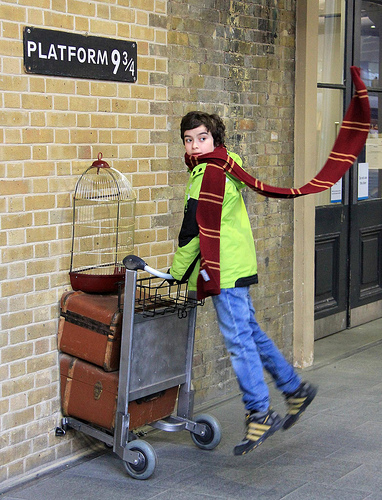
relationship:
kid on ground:
[165, 110, 317, 455] [4, 318, 379, 498]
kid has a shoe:
[165, 110, 317, 455] [277, 380, 321, 432]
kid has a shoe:
[165, 110, 317, 455] [231, 404, 285, 458]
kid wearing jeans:
[165, 110, 317, 455] [208, 278, 314, 422]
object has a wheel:
[60, 258, 232, 483] [121, 438, 160, 477]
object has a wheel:
[60, 258, 232, 483] [187, 414, 222, 452]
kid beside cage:
[165, 110, 317, 455] [67, 151, 142, 294]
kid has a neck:
[165, 110, 317, 455] [184, 153, 221, 167]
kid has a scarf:
[165, 110, 317, 455] [167, 67, 377, 309]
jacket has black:
[165, 149, 264, 294] [172, 206, 260, 288]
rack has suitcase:
[60, 258, 232, 483] [58, 290, 129, 372]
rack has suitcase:
[60, 258, 232, 483] [53, 351, 183, 437]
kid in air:
[165, 110, 317, 455] [0, 9, 380, 497]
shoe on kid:
[277, 380, 321, 432] [165, 110, 317, 455]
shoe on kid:
[231, 404, 285, 458] [165, 110, 317, 455]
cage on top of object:
[67, 151, 142, 294] [60, 258, 232, 483]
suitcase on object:
[58, 290, 129, 372] [60, 258, 232, 483]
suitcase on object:
[53, 351, 183, 437] [60, 258, 232, 483]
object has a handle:
[60, 258, 232, 483] [120, 254, 193, 281]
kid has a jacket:
[165, 110, 317, 455] [165, 149, 264, 294]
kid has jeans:
[165, 110, 317, 455] [208, 278, 314, 422]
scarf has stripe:
[167, 67, 377, 309] [325, 148, 356, 160]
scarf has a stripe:
[167, 67, 377, 309] [336, 115, 372, 127]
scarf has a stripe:
[167, 67, 377, 309] [257, 174, 269, 192]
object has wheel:
[60, 258, 232, 483] [121, 438, 160, 477]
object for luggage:
[60, 258, 232, 483] [53, 351, 183, 437]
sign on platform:
[21, 23, 143, 84] [6, 5, 378, 499]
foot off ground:
[231, 404, 285, 458] [4, 318, 379, 498]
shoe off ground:
[277, 380, 321, 432] [4, 318, 379, 498]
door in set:
[312, 0, 350, 351] [314, 3, 380, 350]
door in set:
[346, 4, 380, 329] [314, 3, 380, 350]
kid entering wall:
[165, 110, 317, 455] [0, 1, 306, 491]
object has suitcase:
[60, 258, 232, 483] [58, 290, 129, 372]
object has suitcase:
[60, 258, 232, 483] [53, 351, 183, 437]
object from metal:
[116, 436, 158, 481] [60, 258, 232, 483]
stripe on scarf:
[325, 148, 356, 160] [167, 67, 377, 309]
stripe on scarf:
[336, 115, 372, 127] [167, 67, 377, 309]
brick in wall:
[111, 94, 140, 115] [0, 1, 306, 491]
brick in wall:
[148, 69, 175, 87] [0, 1, 306, 491]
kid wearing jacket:
[165, 110, 317, 455] [165, 149, 264, 294]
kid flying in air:
[165, 110, 317, 455] [0, 9, 380, 497]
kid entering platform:
[165, 110, 317, 455] [6, 5, 378, 499]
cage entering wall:
[67, 151, 142, 294] [0, 1, 306, 491]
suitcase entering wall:
[58, 290, 129, 372] [0, 1, 306, 491]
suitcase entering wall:
[53, 351, 183, 437] [0, 1, 306, 491]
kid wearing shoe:
[165, 110, 317, 455] [277, 380, 321, 432]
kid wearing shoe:
[165, 110, 317, 455] [231, 404, 285, 458]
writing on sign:
[28, 37, 112, 66] [21, 23, 143, 84]